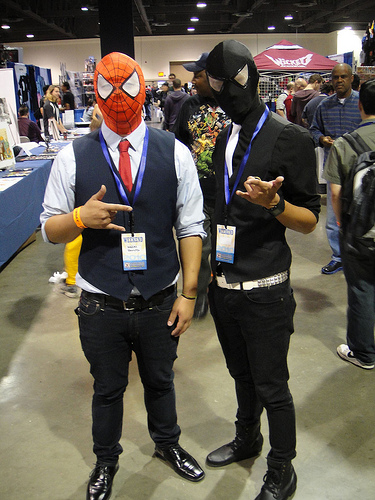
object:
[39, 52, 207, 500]
man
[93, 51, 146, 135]
mask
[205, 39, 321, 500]
man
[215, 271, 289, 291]
belt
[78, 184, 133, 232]
hand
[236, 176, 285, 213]
hand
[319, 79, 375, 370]
man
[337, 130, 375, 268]
backpack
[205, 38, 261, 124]
mask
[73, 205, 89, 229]
wristband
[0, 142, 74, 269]
table cloth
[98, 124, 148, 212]
lanyard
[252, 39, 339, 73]
tent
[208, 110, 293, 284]
vest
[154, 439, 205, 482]
shoe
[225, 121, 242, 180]
tie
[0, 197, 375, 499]
sidewalk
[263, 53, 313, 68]
logo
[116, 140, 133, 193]
tie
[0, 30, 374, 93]
wall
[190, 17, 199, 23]
light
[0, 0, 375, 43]
ceiling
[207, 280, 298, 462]
pants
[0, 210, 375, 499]
floor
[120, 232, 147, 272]
tag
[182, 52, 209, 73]
cap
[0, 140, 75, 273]
table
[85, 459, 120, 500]
shoe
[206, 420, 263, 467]
boot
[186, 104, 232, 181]
design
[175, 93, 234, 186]
shirt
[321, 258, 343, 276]
shoe